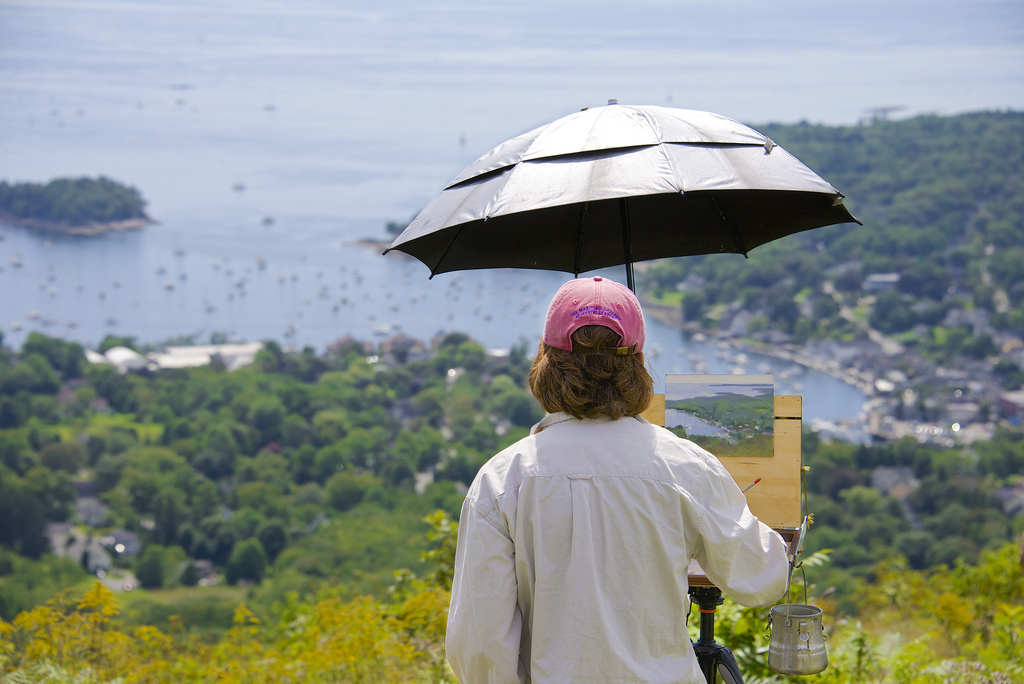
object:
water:
[2, 7, 1017, 441]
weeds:
[2, 534, 1024, 684]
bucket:
[767, 605, 828, 676]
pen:
[742, 476, 762, 494]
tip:
[755, 477, 761, 484]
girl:
[443, 276, 791, 682]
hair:
[528, 326, 654, 422]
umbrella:
[381, 99, 861, 299]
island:
[0, 175, 147, 237]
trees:
[0, 175, 150, 237]